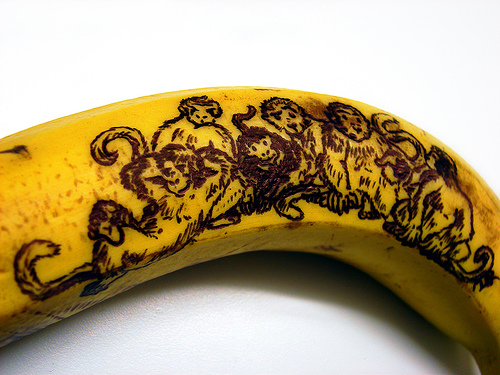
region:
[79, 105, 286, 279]
a banana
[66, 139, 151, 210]
a banana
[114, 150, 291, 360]
a banana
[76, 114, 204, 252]
a banana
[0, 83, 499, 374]
a yellow banana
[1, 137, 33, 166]
banana with brown spot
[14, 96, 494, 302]
six monkey pictures on banana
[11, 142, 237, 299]
brown and yellow monkey lying on his back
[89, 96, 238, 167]
a brown and yellow monkey observing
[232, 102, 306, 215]
A playful yellow and brown monkey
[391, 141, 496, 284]
A monkey looking to his left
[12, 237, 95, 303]
a long curl tail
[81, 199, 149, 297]
a monkey with his leg cross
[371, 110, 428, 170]
a monkey with a S shape tail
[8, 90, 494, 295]
family of lions on bananas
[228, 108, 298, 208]
one black monkey in middle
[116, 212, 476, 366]
shadow of banana on white plate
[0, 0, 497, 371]
yellow banana on white plate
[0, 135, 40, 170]
brown spot on banana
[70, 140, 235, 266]
monkey lying on back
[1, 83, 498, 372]
tip and tail of banana not visible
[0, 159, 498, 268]
light brown spots on bananas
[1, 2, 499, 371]
light reflecting on plate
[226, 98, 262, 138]
dark tail hanging above monkey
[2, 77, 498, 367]
yellow banana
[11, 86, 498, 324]
black drawing on the banana peel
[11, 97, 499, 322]
drawing of monkeys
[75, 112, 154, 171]
tail is curled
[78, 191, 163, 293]
one leg resting on the other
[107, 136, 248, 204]
arms behind the head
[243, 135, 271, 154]
two black dots for eyes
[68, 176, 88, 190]
small brown dot on the peel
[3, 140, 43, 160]
black mark on the banana peel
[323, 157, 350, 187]
black lines on the arm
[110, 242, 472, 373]
a black shadow under the banana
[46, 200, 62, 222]
a brown spot on the banana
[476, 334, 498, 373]
the stem of a banana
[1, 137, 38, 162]
a scratch on the banana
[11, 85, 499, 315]
a black drawing on the banana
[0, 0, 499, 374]
a white table under the banana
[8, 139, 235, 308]
a monkey on the banana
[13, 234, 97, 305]
the tail of a monkey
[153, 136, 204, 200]
the head of a monkey